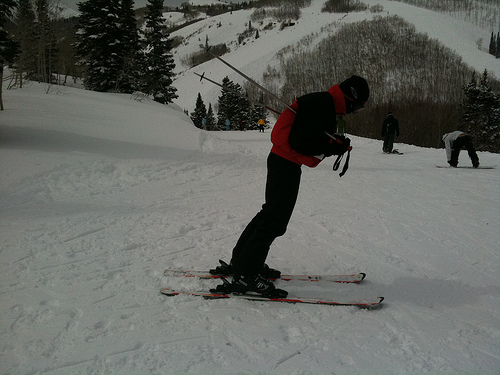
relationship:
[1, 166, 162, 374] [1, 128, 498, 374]
tracks in snow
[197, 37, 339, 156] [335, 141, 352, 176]
ski poles have straps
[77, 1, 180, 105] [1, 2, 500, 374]
trees tower over snow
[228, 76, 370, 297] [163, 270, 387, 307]
people wearing skis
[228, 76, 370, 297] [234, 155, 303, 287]
people wears black ski pants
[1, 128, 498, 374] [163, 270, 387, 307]
snow on top of skis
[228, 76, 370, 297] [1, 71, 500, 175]
people going downhill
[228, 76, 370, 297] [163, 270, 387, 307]
people on skis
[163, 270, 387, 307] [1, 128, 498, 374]
red skis covered in snow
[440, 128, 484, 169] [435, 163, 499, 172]
person on a snowboard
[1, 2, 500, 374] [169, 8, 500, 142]
snow covering mountain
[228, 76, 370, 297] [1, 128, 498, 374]
people stands in snow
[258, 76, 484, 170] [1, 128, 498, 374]
people in snow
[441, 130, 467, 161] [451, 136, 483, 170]
grey jacket with black pants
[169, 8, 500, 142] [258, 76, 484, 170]
mountain beyond people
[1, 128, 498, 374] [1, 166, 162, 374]
snow covered in tracks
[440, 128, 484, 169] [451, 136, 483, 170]
person wearing black pants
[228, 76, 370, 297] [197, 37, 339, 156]
people holding ski poles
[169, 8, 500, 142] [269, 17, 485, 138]
mountain covered in trees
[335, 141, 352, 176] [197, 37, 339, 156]
straps on ski poles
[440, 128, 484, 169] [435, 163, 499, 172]
person straps feet to snowboard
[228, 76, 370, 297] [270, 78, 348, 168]
people wears jacket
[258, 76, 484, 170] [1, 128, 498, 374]
people on snow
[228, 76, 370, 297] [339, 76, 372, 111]
people wears black ski mask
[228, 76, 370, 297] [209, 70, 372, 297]
people on winter clothes